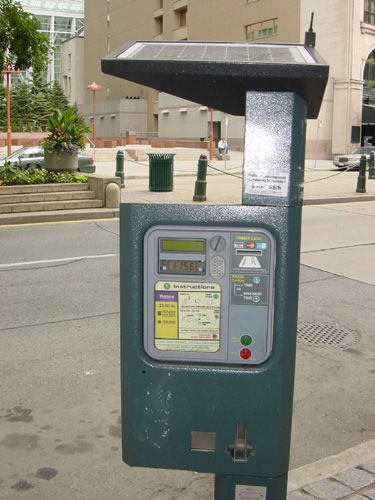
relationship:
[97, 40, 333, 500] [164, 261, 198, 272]
meter has time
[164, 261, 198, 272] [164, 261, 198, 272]
time displays time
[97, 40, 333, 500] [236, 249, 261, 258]
meter has card slot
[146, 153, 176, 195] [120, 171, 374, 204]
trash can sits on sidewalk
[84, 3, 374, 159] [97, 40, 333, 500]
building behind meter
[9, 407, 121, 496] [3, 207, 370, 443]
water on street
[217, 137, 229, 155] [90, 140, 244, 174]
person in public area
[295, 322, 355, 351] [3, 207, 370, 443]
sewer grate in road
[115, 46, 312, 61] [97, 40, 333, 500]
solar panel powers meter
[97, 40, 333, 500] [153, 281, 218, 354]
meter has instructions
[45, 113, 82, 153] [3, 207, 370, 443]
plants next to road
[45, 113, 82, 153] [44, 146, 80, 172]
plant in planter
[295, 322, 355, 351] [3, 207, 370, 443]
drain on street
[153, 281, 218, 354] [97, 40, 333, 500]
instructions on box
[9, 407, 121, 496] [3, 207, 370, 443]
stains on street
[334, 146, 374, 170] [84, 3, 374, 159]
car next to building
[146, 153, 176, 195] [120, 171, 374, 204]
trash can on sidewalk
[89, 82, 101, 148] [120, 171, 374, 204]
street light on sidewalk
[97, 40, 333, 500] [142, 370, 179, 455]
unit has scrapes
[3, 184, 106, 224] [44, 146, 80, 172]
steps near planter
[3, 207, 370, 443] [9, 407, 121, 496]
street has stains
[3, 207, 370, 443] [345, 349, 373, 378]
street has stains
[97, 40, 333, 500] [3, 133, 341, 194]
meter in front of plaza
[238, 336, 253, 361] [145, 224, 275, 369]
buttons on panel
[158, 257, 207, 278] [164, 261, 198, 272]
window shows time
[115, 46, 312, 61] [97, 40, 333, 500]
solar panel above meter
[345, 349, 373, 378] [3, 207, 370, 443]
stains on street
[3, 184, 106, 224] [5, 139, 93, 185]
steps go to plantings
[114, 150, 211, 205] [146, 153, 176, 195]
pillars around garbage can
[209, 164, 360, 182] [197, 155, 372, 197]
chain links pillars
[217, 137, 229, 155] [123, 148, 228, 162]
person on steps